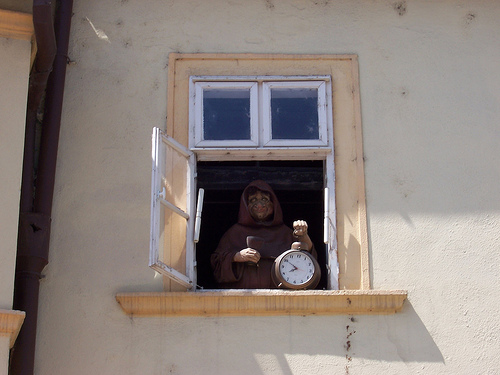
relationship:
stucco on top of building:
[72, 22, 146, 275] [21, 9, 474, 150]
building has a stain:
[21, 9, 474, 150] [121, 38, 133, 48]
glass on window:
[272, 91, 316, 141] [260, 77, 330, 149]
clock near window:
[271, 249, 322, 288] [260, 77, 330, 149]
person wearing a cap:
[215, 181, 314, 287] [214, 228, 272, 289]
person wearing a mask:
[215, 181, 314, 287] [243, 190, 277, 220]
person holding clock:
[215, 181, 274, 287] [271, 249, 322, 288]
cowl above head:
[198, 159, 318, 184] [237, 180, 276, 228]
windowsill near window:
[114, 286, 409, 315] [152, 130, 198, 276]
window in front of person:
[152, 130, 198, 276] [215, 181, 274, 287]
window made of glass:
[260, 77, 330, 149] [272, 91, 316, 141]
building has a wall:
[21, 9, 474, 150] [375, 12, 497, 285]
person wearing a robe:
[215, 181, 274, 287] [221, 221, 286, 259]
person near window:
[215, 181, 274, 287] [152, 130, 198, 276]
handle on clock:
[283, 266, 299, 275] [271, 249, 322, 288]